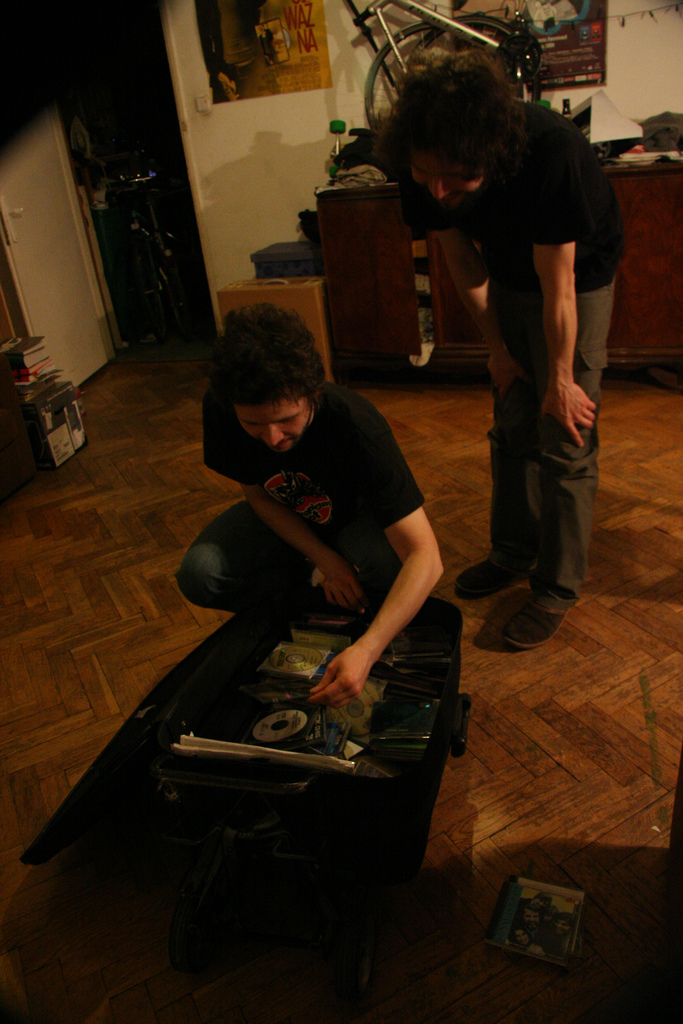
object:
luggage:
[18, 592, 466, 928]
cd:
[253, 710, 308, 743]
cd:
[258, 640, 331, 681]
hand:
[544, 364, 597, 447]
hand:
[308, 635, 381, 711]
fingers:
[307, 659, 360, 711]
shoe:
[500, 592, 579, 649]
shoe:
[454, 558, 531, 604]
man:
[388, 47, 625, 650]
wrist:
[349, 627, 385, 663]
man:
[174, 304, 446, 707]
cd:
[482, 871, 585, 973]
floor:
[0, 361, 683, 1024]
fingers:
[568, 399, 596, 446]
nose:
[260, 424, 284, 448]